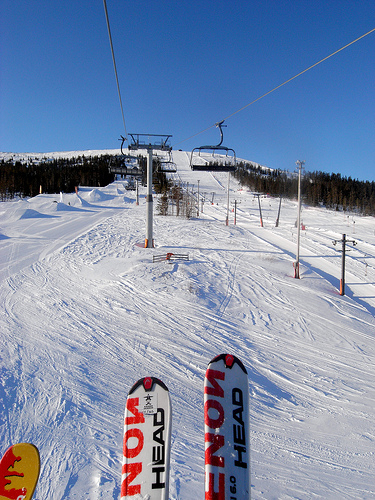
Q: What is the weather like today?
A: It is clear.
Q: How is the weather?
A: It is clear.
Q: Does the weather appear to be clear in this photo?
A: Yes, it is clear.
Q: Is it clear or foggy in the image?
A: It is clear.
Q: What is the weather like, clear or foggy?
A: It is clear.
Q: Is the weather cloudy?
A: No, it is clear.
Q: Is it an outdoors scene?
A: Yes, it is outdoors.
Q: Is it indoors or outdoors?
A: It is outdoors.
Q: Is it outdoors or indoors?
A: It is outdoors.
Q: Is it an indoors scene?
A: No, it is outdoors.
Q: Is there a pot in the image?
A: No, there are no pots.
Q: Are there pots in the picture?
A: No, there are no pots.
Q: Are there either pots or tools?
A: No, there are no pots or tools.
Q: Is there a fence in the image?
A: No, there are no fences.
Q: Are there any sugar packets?
A: No, there are no sugar packets.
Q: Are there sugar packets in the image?
A: No, there are no sugar packets.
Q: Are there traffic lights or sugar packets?
A: No, there are no sugar packets or traffic lights.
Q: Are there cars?
A: No, there are no cars.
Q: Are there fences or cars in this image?
A: No, there are no cars or fences.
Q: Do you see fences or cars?
A: No, there are no cars or fences.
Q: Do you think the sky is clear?
A: Yes, the sky is clear.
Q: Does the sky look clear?
A: Yes, the sky is clear.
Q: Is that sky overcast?
A: No, the sky is clear.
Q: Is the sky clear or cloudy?
A: The sky is clear.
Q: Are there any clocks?
A: No, there are no clocks.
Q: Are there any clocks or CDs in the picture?
A: No, there are no clocks or cds.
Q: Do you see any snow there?
A: Yes, there is snow.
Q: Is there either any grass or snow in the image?
A: Yes, there is snow.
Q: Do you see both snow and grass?
A: No, there is snow but no grass.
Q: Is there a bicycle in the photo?
A: No, there are no bicycles.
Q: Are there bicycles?
A: No, there are no bicycles.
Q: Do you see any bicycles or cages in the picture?
A: No, there are no bicycles or cages.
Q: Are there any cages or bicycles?
A: No, there are no bicycles or cages.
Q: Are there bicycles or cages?
A: No, there are no bicycles or cages.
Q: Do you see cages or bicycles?
A: No, there are no bicycles or cages.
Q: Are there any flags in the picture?
A: No, there are no flags.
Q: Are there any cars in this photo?
A: No, there are no cars.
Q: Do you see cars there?
A: No, there are no cars.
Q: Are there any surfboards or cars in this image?
A: No, there are no cars or surfboards.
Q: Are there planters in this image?
A: No, there are no planters.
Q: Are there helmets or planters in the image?
A: No, there are no planters or helmets.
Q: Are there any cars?
A: No, there are no cars.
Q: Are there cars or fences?
A: No, there are no cars or fences.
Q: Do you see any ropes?
A: No, there are no ropes.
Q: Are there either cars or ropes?
A: No, there are no ropes or cars.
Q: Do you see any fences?
A: No, there are no fences.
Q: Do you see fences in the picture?
A: No, there are no fences.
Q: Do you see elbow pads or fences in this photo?
A: No, there are no fences or elbow pads.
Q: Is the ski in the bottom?
A: Yes, the ski is in the bottom of the image.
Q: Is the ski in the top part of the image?
A: No, the ski is in the bottom of the image.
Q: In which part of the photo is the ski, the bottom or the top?
A: The ski is in the bottom of the image.